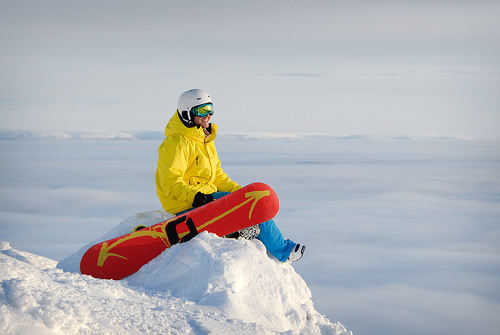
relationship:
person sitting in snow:
[156, 85, 305, 265] [140, 237, 320, 325]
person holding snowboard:
[156, 85, 305, 265] [80, 180, 281, 280]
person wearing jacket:
[156, 85, 305, 265] [153, 115, 239, 212]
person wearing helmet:
[156, 85, 305, 265] [176, 87, 215, 122]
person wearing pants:
[156, 85, 305, 265] [211, 186, 298, 264]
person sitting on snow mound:
[156, 85, 305, 265] [59, 210, 311, 332]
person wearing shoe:
[156, 85, 305, 265] [281, 240, 305, 267]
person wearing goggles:
[156, 85, 305, 265] [192, 103, 218, 119]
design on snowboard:
[89, 185, 275, 266] [80, 180, 281, 280]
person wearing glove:
[156, 85, 305, 265] [190, 186, 213, 210]